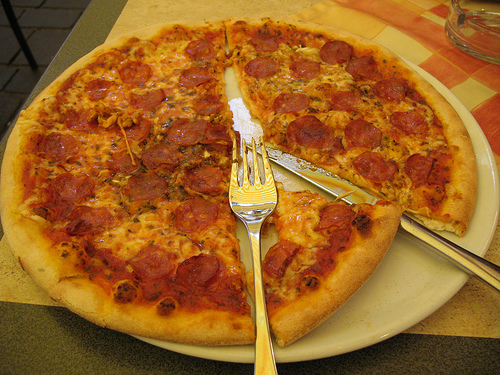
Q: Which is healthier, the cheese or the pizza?
A: The cheese is healthier than the pizza.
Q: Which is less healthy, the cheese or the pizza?
A: The pizza is less healthy than the cheese.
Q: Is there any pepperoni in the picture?
A: Yes, there is pepperoni.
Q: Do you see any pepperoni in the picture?
A: Yes, there is pepperoni.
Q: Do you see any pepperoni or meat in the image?
A: Yes, there is pepperoni.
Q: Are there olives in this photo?
A: No, there are no olives.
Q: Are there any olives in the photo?
A: No, there are no olives.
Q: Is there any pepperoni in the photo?
A: Yes, there is pepperoni.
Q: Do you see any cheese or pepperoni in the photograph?
A: Yes, there is pepperoni.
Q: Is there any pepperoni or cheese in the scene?
A: Yes, there is pepperoni.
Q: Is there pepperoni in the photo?
A: Yes, there is pepperoni.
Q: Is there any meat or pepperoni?
A: Yes, there is pepperoni.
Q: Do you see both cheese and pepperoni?
A: Yes, there are both pepperoni and cheese.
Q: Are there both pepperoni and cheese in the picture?
A: Yes, there are both pepperoni and cheese.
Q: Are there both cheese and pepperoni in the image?
A: Yes, there are both pepperoni and cheese.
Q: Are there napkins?
A: No, there are no napkins.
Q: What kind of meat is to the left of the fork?
A: The meat is pepperoni.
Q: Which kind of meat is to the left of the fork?
A: The meat is pepperoni.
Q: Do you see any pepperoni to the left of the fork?
A: Yes, there is pepperoni to the left of the fork.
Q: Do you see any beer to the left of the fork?
A: No, there is pepperoni to the left of the fork.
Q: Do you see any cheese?
A: Yes, there is cheese.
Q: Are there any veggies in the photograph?
A: No, there are no veggies.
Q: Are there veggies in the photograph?
A: No, there are no veggies.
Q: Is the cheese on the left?
A: Yes, the cheese is on the left of the image.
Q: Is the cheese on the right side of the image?
A: No, the cheese is on the left of the image.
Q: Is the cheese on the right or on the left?
A: The cheese is on the left of the image.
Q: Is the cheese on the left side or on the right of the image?
A: The cheese is on the left of the image.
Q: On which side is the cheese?
A: The cheese is on the left of the image.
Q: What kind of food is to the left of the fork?
A: The food is cheese.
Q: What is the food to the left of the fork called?
A: The food is cheese.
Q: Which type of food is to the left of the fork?
A: The food is cheese.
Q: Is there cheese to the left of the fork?
A: Yes, there is cheese to the left of the fork.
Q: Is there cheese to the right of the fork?
A: No, the cheese is to the left of the fork.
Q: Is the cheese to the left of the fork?
A: Yes, the cheese is to the left of the fork.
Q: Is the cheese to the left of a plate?
A: No, the cheese is to the left of the fork.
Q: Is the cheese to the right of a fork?
A: No, the cheese is to the left of a fork.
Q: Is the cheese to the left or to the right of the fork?
A: The cheese is to the left of the fork.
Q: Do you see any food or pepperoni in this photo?
A: Yes, there is pepperoni.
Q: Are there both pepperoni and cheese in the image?
A: Yes, there are both pepperoni and cheese.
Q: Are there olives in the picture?
A: No, there are no olives.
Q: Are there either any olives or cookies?
A: No, there are no olives or cookies.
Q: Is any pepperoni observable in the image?
A: Yes, there is pepperoni.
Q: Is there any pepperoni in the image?
A: Yes, there is pepperoni.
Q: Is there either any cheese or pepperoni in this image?
A: Yes, there is pepperoni.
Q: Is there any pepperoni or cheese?
A: Yes, there is pepperoni.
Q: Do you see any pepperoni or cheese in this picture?
A: Yes, there is pepperoni.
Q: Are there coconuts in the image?
A: No, there are no coconuts.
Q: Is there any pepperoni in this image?
A: Yes, there is pepperoni.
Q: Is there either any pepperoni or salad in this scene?
A: Yes, there is pepperoni.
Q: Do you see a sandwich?
A: No, there are no sandwiches.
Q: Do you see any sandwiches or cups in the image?
A: No, there are no sandwiches or cups.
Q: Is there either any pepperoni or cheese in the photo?
A: Yes, there is pepperoni.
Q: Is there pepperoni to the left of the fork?
A: Yes, there is pepperoni to the left of the fork.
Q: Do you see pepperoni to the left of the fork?
A: Yes, there is pepperoni to the left of the fork.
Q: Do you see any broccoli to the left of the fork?
A: No, there is pepperoni to the left of the fork.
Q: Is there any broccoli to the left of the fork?
A: No, there is pepperoni to the left of the fork.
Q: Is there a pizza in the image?
A: Yes, there is a pizza.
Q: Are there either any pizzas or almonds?
A: Yes, there is a pizza.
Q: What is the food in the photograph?
A: The food is a pizza.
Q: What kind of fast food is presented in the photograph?
A: The fast food is a pizza.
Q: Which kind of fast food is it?
A: The food is a pizza.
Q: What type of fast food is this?
A: This is a pizza.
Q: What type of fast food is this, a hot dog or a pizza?
A: This is a pizza.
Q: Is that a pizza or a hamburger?
A: That is a pizza.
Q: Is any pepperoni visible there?
A: Yes, there is pepperoni.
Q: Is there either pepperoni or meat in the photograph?
A: Yes, there is pepperoni.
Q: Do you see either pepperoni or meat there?
A: Yes, there is pepperoni.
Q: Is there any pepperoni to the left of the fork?
A: Yes, there is pepperoni to the left of the fork.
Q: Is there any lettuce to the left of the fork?
A: No, there is pepperoni to the left of the fork.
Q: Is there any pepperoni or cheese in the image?
A: Yes, there is pepperoni.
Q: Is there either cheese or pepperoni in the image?
A: Yes, there is pepperoni.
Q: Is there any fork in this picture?
A: Yes, there is a fork.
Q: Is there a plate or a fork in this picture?
A: Yes, there is a fork.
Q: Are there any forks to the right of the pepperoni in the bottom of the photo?
A: Yes, there is a fork to the right of the pepperoni.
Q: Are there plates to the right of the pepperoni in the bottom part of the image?
A: No, there is a fork to the right of the pepperoni.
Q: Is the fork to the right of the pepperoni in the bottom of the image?
A: Yes, the fork is to the right of the pepperoni.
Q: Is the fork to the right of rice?
A: No, the fork is to the right of the pepperoni.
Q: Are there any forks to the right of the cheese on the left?
A: Yes, there is a fork to the right of the cheese.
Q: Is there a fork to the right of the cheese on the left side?
A: Yes, there is a fork to the right of the cheese.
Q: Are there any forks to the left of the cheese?
A: No, the fork is to the right of the cheese.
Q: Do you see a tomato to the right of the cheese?
A: No, there is a fork to the right of the cheese.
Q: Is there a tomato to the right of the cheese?
A: No, there is a fork to the right of the cheese.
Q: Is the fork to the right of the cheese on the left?
A: Yes, the fork is to the right of the cheese.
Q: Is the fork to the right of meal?
A: No, the fork is to the right of the cheese.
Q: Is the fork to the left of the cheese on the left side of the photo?
A: No, the fork is to the right of the cheese.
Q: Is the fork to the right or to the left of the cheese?
A: The fork is to the right of the cheese.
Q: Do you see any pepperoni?
A: Yes, there is pepperoni.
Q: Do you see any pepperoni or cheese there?
A: Yes, there is pepperoni.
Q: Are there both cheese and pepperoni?
A: Yes, there are both pepperoni and cheese.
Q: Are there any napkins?
A: No, there are no napkins.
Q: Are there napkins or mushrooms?
A: No, there are no napkins or mushrooms.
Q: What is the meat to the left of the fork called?
A: The meat is pepperoni.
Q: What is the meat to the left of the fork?
A: The meat is pepperoni.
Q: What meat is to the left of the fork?
A: The meat is pepperoni.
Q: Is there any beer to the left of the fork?
A: No, there is pepperoni to the left of the fork.